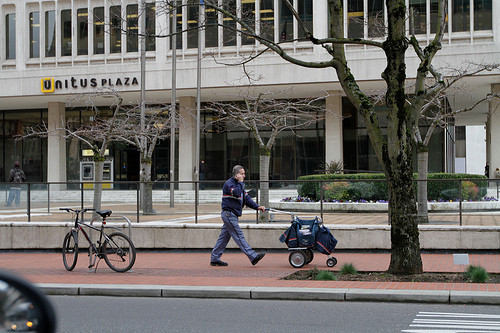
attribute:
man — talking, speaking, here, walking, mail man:
[209, 163, 268, 267]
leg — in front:
[227, 216, 266, 266]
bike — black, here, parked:
[56, 205, 139, 273]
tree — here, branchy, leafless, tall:
[109, 0, 500, 276]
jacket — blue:
[220, 177, 259, 217]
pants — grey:
[209, 208, 261, 262]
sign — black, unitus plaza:
[39, 75, 140, 94]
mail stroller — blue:
[279, 213, 338, 267]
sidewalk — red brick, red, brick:
[0, 248, 499, 292]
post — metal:
[89, 213, 134, 267]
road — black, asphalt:
[32, 291, 500, 332]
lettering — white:
[400, 310, 499, 332]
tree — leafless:
[13, 87, 163, 222]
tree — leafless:
[95, 99, 193, 219]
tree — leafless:
[183, 86, 349, 224]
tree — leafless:
[348, 53, 498, 226]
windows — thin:
[4, 3, 499, 71]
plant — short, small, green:
[469, 269, 491, 284]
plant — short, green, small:
[340, 263, 360, 274]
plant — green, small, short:
[311, 270, 338, 281]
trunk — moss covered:
[366, 134, 428, 280]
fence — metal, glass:
[0, 182, 500, 225]